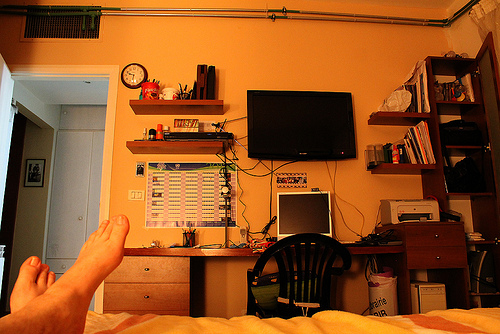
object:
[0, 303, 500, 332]
bed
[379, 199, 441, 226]
printer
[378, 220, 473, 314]
desk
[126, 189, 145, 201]
light switch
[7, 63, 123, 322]
trim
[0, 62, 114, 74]
doorway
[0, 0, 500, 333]
room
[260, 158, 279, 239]
electronic wires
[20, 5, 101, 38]
air vent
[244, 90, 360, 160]
tv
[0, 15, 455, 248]
wall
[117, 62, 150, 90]
clock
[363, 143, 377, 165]
books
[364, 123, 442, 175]
shelf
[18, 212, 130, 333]
feet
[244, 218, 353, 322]
chair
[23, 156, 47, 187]
picture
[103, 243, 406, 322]
desk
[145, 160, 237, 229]
poster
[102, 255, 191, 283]
drawer